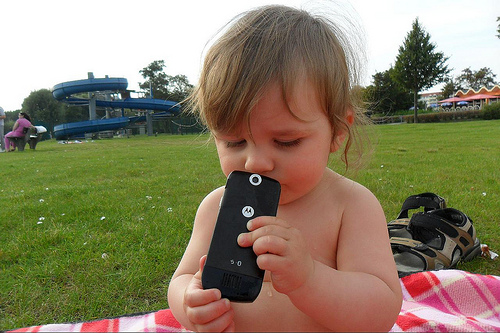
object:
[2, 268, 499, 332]
blanket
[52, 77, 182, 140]
slide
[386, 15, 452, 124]
tree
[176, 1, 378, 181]
hair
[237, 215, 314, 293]
hand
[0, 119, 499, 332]
grass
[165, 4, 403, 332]
baby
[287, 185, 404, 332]
arm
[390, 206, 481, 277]
shoes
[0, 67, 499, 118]
ground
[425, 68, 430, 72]
leaves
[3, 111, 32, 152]
person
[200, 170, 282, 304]
phone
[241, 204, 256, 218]
emblem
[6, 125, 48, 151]
bench